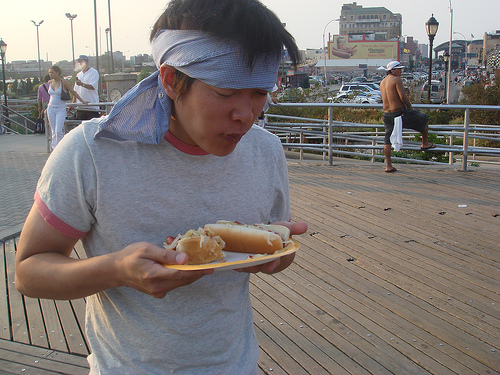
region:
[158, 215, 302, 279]
Hot dogs on plate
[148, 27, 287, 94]
Bandana tied on head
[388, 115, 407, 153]
White t-shirt hanging from pocket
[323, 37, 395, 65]
Billboard advertising hotdog and soda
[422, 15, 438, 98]
Lamp post on street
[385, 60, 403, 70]
White baseball cap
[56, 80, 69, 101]
Black purse on shoulder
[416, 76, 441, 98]
Van driving on road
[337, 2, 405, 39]
Tall building on horizon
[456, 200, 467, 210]
Litter on boardwalk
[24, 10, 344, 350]
the man is eating hotdogs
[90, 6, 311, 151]
the man is wearing a blue bandana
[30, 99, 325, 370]
the man is wearing a gray shirt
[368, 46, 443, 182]
the man is wearing a white hat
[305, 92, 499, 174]
the railing is gray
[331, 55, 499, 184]
the man has his foot on the railing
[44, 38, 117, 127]
the man in the white shirt is smoking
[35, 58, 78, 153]
the woman is wearing white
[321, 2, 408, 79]
there is a billboard on the background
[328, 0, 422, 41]
there is a building in the background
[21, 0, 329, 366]
A boy eating hot dogs.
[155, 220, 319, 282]
Plate with hot dogs.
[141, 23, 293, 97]
Scarf tied around boy's head.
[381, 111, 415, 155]
White shirt hanging out of man's back pocket.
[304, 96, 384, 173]
Metal railing along boardwalk.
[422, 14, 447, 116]
Lamp post on boardwalk.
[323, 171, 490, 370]
Wood planks of boardwalk.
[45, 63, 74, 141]
Woman carrying black purse.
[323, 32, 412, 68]
A yellow and red billboard.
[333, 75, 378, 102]
Cars in a parking lot.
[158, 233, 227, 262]
Half-eaten hot dog on plate.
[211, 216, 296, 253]
Complete hot dog on plate.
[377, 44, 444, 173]
Man with no shirt on wearing a white hat.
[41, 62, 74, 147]
Woman wearing white pants and tank top.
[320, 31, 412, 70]
Red and yellow hot dog advertisement sign.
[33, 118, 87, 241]
Left t-shirt sleeve of man eating hot dogs.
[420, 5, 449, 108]
Black light pole in front of man with no shirt on.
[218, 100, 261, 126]
Nose of man eating hot dogs on plate.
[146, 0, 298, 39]
Black hair of man eating hot dogs on plate.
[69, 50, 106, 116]
Man in white t-shirt behind woman wearing white pants.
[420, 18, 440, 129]
Light pole surrounded by shrubs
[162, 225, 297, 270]
Hotdogs on a paper plate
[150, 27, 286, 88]
Head band made out of a shirt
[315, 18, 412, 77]
Advertising billboard on the side of building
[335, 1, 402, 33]
Building behind a large billboard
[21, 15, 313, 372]
Asian Man eating a plate full of hotdogs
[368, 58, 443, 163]
Man with no shirt on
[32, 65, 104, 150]
3 people standing in a group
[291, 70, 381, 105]
Parking Lot with many cars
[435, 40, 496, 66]
Several buildings in a row